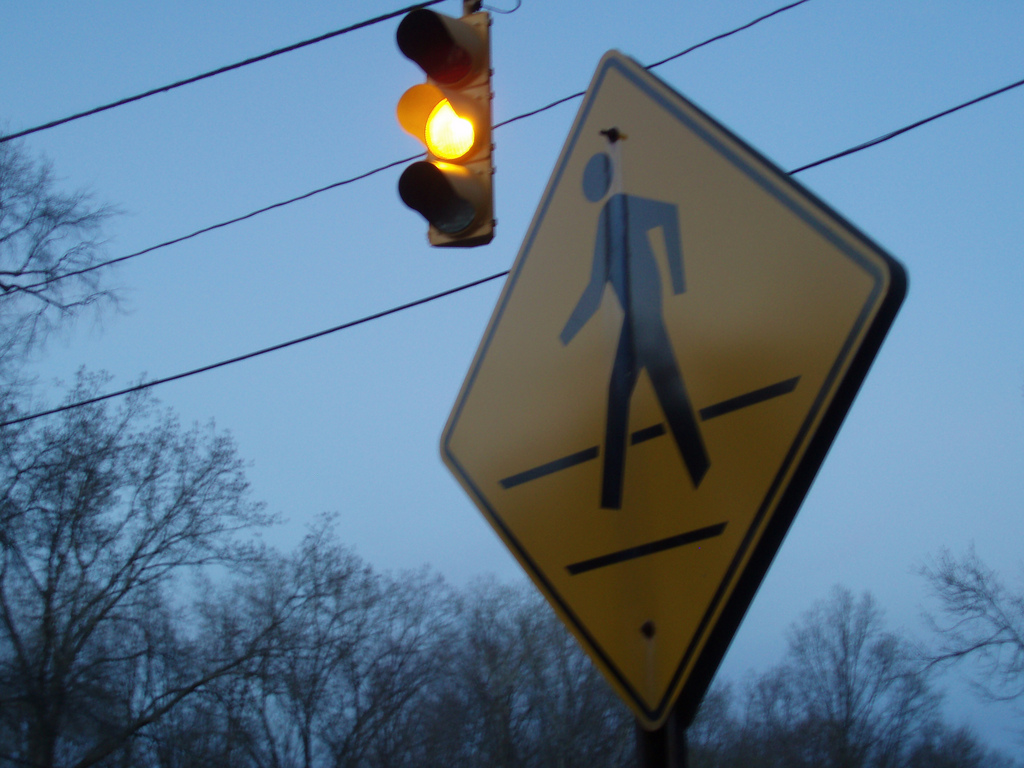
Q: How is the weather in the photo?
A: It is cloudy.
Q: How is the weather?
A: It is cloudy.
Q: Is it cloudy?
A: Yes, it is cloudy.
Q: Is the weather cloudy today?
A: Yes, it is cloudy.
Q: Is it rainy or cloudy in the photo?
A: It is cloudy.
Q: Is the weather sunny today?
A: No, it is cloudy.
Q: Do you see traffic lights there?
A: Yes, there is a traffic light.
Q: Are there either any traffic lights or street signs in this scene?
A: Yes, there is a traffic light.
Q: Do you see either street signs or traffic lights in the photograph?
A: Yes, there is a traffic light.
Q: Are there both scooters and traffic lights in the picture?
A: No, there is a traffic light but no scooters.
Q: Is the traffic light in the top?
A: Yes, the traffic light is in the top of the image.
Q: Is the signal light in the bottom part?
A: No, the signal light is in the top of the image.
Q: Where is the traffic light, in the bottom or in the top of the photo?
A: The traffic light is in the top of the image.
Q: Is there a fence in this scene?
A: No, there are no fences.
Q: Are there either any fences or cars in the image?
A: No, there are no fences or cars.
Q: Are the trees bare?
A: Yes, the trees are bare.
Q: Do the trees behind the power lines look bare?
A: Yes, the trees are bare.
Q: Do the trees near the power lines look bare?
A: Yes, the trees are bare.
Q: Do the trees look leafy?
A: No, the trees are bare.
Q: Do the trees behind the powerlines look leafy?
A: No, the trees are bare.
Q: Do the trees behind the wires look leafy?
A: No, the trees are bare.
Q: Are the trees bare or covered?
A: The trees are bare.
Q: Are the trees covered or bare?
A: The trees are bare.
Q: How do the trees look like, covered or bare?
A: The trees are bare.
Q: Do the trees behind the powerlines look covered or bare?
A: The trees are bare.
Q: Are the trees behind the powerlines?
A: Yes, the trees are behind the powerlines.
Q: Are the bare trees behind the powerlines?
A: Yes, the trees are behind the powerlines.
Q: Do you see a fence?
A: No, there are no fences.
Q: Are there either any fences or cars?
A: No, there are no fences or cars.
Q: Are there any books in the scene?
A: No, there are no books.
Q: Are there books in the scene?
A: No, there are no books.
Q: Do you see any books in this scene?
A: No, there are no books.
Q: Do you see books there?
A: No, there are no books.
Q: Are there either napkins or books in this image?
A: No, there are no books or napkins.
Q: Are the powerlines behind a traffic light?
A: Yes, the powerlines are behind a traffic light.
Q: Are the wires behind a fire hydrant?
A: No, the wires are behind a traffic light.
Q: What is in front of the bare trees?
A: The power lines are in front of the trees.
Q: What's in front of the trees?
A: The power lines are in front of the trees.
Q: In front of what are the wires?
A: The wires are in front of the trees.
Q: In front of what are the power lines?
A: The wires are in front of the trees.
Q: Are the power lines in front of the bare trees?
A: Yes, the power lines are in front of the trees.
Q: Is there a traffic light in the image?
A: Yes, there is a traffic light.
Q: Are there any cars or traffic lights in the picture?
A: Yes, there is a traffic light.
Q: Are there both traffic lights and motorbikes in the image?
A: No, there is a traffic light but no motorcycles.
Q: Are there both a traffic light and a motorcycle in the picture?
A: No, there is a traffic light but no motorcycles.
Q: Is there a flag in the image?
A: No, there are no flags.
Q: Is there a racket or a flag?
A: No, there are no flags or rackets.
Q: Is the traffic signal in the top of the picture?
A: Yes, the traffic signal is in the top of the image.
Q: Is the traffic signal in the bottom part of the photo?
A: No, the traffic signal is in the top of the image.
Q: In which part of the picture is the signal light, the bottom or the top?
A: The signal light is in the top of the image.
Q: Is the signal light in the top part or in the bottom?
A: The signal light is in the top of the image.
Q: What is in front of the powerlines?
A: The traffic signal is in front of the powerlines.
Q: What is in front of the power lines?
A: The traffic signal is in front of the powerlines.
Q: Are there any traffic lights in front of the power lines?
A: Yes, there is a traffic light in front of the power lines.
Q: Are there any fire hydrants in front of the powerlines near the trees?
A: No, there is a traffic light in front of the power lines.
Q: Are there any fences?
A: No, there are no fences.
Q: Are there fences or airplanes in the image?
A: No, there are no fences or airplanes.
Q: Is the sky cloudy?
A: Yes, the sky is cloudy.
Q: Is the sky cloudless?
A: No, the sky is cloudy.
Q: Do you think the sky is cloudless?
A: No, the sky is cloudy.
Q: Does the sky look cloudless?
A: No, the sky is cloudy.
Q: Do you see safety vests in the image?
A: No, there are no safety vests.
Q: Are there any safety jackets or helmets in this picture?
A: No, there are no safety jackets or helmets.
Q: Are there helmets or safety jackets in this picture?
A: No, there are no safety jackets or helmets.